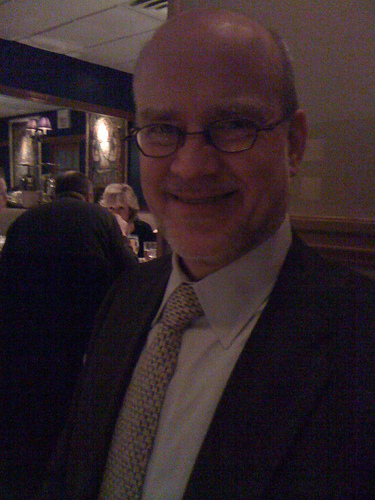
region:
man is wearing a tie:
[128, 282, 187, 497]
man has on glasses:
[102, 100, 320, 151]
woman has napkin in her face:
[110, 208, 139, 237]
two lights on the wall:
[18, 108, 71, 148]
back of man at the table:
[22, 169, 121, 270]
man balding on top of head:
[143, 7, 289, 67]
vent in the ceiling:
[123, 2, 198, 20]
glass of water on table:
[145, 240, 161, 276]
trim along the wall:
[298, 209, 372, 246]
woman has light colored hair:
[90, 173, 149, 215]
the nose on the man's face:
[169, 124, 222, 179]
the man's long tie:
[94, 276, 214, 498]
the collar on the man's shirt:
[138, 213, 303, 345]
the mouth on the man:
[157, 182, 245, 208]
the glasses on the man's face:
[120, 109, 292, 156]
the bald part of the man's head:
[125, 6, 290, 81]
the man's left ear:
[287, 104, 309, 176]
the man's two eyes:
[137, 112, 260, 141]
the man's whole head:
[124, 5, 308, 261]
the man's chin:
[160, 218, 232, 263]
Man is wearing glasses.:
[119, 108, 277, 177]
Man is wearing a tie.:
[103, 285, 211, 494]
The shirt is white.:
[189, 280, 256, 336]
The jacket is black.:
[266, 333, 370, 453]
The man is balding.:
[116, 6, 300, 119]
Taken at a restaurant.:
[0, 106, 371, 494]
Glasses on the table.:
[127, 229, 157, 261]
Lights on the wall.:
[23, 118, 65, 136]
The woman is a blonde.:
[103, 177, 143, 205]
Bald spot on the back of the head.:
[49, 162, 100, 186]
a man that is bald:
[21, 10, 369, 406]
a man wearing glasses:
[94, 8, 346, 241]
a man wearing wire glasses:
[89, 6, 370, 282]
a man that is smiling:
[102, 10, 345, 278]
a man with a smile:
[85, 18, 320, 275]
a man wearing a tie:
[57, 12, 319, 490]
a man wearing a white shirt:
[33, 7, 370, 437]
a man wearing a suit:
[29, 4, 364, 498]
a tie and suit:
[29, 234, 373, 491]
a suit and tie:
[73, 235, 356, 489]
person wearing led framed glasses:
[117, 110, 295, 159]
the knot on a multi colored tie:
[153, 282, 204, 336]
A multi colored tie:
[126, 361, 154, 452]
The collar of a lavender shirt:
[199, 283, 244, 351]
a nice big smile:
[160, 180, 249, 218]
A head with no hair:
[116, 0, 313, 103]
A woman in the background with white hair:
[100, 181, 140, 224]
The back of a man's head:
[47, 166, 98, 210]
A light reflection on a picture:
[90, 116, 118, 163]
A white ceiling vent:
[122, 0, 177, 19]